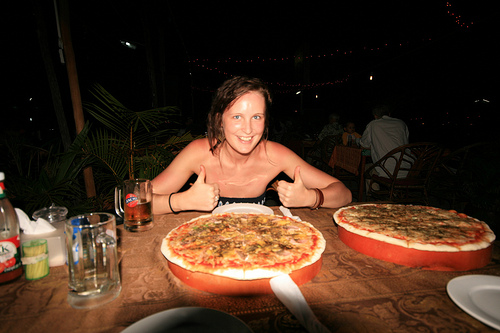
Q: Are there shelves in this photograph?
A: No, there are no shelves.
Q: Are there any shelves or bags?
A: No, there are no shelves or bags.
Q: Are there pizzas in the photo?
A: Yes, there is a pizza.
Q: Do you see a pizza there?
A: Yes, there is a pizza.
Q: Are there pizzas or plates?
A: Yes, there is a pizza.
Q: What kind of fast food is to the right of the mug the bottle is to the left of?
A: The food is a pizza.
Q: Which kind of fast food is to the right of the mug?
A: The food is a pizza.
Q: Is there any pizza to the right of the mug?
A: Yes, there is a pizza to the right of the mug.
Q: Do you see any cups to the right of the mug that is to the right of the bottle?
A: No, there is a pizza to the right of the mug.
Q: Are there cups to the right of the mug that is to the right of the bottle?
A: No, there is a pizza to the right of the mug.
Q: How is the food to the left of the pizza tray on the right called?
A: The food is a pizza.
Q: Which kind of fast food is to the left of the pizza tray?
A: The food is a pizza.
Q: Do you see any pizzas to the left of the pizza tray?
A: Yes, there is a pizza to the left of the pizza tray.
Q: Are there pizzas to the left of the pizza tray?
A: Yes, there is a pizza to the left of the pizza tray.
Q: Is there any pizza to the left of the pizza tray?
A: Yes, there is a pizza to the left of the pizza tray.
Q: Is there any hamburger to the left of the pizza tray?
A: No, there is a pizza to the left of the pizza tray.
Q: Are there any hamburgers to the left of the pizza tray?
A: No, there is a pizza to the left of the pizza tray.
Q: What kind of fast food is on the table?
A: The food is a pizza.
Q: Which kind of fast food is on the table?
A: The food is a pizza.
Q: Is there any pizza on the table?
A: Yes, there is a pizza on the table.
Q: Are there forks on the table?
A: No, there is a pizza on the table.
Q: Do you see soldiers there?
A: No, there are no soldiers.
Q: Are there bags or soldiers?
A: No, there are no soldiers or bags.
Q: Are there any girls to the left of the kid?
A: Yes, there is a girl to the left of the kid.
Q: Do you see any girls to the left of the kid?
A: Yes, there is a girl to the left of the kid.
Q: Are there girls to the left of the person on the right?
A: Yes, there is a girl to the left of the kid.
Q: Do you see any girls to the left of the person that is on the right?
A: Yes, there is a girl to the left of the kid.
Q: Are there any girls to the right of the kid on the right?
A: No, the girl is to the left of the child.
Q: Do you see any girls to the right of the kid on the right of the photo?
A: No, the girl is to the left of the child.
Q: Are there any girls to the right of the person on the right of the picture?
A: No, the girl is to the left of the child.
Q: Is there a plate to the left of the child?
A: No, there is a girl to the left of the child.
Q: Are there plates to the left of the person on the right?
A: No, there is a girl to the left of the child.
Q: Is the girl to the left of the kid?
A: Yes, the girl is to the left of the kid.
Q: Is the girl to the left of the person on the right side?
A: Yes, the girl is to the left of the kid.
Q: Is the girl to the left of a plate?
A: No, the girl is to the left of the kid.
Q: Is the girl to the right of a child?
A: No, the girl is to the left of a child.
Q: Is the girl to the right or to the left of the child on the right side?
A: The girl is to the left of the kid.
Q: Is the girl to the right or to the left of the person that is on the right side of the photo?
A: The girl is to the left of the kid.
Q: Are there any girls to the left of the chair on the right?
A: Yes, there is a girl to the left of the chair.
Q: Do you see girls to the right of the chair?
A: No, the girl is to the left of the chair.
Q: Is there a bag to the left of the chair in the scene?
A: No, there is a girl to the left of the chair.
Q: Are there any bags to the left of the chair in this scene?
A: No, there is a girl to the left of the chair.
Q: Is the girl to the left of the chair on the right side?
A: Yes, the girl is to the left of the chair.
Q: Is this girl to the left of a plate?
A: No, the girl is to the left of the chair.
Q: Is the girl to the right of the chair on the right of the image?
A: No, the girl is to the left of the chair.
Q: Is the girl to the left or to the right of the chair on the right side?
A: The girl is to the left of the chair.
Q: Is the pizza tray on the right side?
A: Yes, the pizza tray is on the right of the image.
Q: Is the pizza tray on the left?
A: No, the pizza tray is on the right of the image.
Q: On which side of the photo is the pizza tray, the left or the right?
A: The pizza tray is on the right of the image.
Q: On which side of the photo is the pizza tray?
A: The pizza tray is on the right of the image.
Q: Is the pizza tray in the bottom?
A: Yes, the pizza tray is in the bottom of the image.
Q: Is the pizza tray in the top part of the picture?
A: No, the pizza tray is in the bottom of the image.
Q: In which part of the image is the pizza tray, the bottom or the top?
A: The pizza tray is in the bottom of the image.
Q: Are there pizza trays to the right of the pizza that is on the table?
A: Yes, there is a pizza tray to the right of the pizza.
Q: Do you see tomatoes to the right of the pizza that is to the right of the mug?
A: No, there is a pizza tray to the right of the pizza.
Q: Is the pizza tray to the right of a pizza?
A: Yes, the pizza tray is to the right of a pizza.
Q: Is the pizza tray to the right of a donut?
A: No, the pizza tray is to the right of a pizza.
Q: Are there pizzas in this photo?
A: Yes, there is a pizza.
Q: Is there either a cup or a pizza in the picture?
A: Yes, there is a pizza.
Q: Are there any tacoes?
A: No, there are no tacoes.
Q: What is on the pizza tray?
A: The pizza is on the pizza tray.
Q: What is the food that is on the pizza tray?
A: The food is a pizza.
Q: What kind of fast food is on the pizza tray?
A: The food is a pizza.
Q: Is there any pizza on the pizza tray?
A: Yes, there is a pizza on the pizza tray.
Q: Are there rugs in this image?
A: No, there are no rugs.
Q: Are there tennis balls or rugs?
A: No, there are no rugs or tennis balls.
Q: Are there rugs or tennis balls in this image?
A: No, there are no rugs or tennis balls.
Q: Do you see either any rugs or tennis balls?
A: No, there are no rugs or tennis balls.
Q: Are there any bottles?
A: Yes, there is a bottle.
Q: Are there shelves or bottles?
A: Yes, there is a bottle.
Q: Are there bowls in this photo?
A: No, there are no bowls.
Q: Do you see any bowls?
A: No, there are no bowls.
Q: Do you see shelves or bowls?
A: No, there are no bowls or shelves.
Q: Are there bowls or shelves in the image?
A: No, there are no bowls or shelves.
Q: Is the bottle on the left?
A: Yes, the bottle is on the left of the image.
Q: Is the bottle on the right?
A: No, the bottle is on the left of the image.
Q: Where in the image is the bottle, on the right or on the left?
A: The bottle is on the left of the image.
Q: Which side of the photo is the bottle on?
A: The bottle is on the left of the image.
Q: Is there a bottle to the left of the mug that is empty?
A: Yes, there is a bottle to the left of the mug.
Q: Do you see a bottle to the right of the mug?
A: No, the bottle is to the left of the mug.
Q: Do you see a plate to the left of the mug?
A: No, there is a bottle to the left of the mug.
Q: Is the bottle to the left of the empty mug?
A: Yes, the bottle is to the left of the mug.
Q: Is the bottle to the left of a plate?
A: No, the bottle is to the left of the mug.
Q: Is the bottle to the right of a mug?
A: No, the bottle is to the left of a mug.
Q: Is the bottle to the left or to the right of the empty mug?
A: The bottle is to the left of the mug.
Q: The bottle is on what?
A: The bottle is on the table.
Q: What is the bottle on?
A: The bottle is on the table.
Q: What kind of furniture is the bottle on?
A: The bottle is on the table.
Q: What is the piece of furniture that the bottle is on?
A: The piece of furniture is a table.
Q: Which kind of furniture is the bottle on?
A: The bottle is on the table.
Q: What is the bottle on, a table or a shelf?
A: The bottle is on a table.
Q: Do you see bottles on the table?
A: Yes, there is a bottle on the table.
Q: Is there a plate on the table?
A: No, there is a bottle on the table.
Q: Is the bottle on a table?
A: Yes, the bottle is on a table.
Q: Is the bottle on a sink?
A: No, the bottle is on a table.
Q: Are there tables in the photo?
A: Yes, there is a table.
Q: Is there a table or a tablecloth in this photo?
A: Yes, there is a table.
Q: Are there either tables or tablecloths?
A: Yes, there is a table.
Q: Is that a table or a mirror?
A: That is a table.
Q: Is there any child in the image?
A: Yes, there is a child.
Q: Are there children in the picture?
A: Yes, there is a child.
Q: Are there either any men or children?
A: Yes, there is a child.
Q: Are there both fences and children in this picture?
A: No, there is a child but no fences.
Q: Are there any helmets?
A: No, there are no helmets.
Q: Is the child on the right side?
A: Yes, the child is on the right of the image.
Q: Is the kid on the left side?
A: No, the kid is on the right of the image.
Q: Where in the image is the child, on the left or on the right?
A: The child is on the right of the image.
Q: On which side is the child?
A: The child is on the right of the image.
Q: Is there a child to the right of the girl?
A: Yes, there is a child to the right of the girl.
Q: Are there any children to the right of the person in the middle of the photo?
A: Yes, there is a child to the right of the girl.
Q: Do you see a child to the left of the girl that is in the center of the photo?
A: No, the child is to the right of the girl.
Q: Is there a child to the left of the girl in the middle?
A: No, the child is to the right of the girl.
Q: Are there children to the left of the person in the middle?
A: No, the child is to the right of the girl.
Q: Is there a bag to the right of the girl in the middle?
A: No, there is a child to the right of the girl.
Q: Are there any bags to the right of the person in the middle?
A: No, there is a child to the right of the girl.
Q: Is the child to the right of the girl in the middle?
A: Yes, the child is to the right of the girl.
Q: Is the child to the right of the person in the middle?
A: Yes, the child is to the right of the girl.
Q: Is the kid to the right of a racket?
A: No, the kid is to the right of the girl.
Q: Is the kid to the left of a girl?
A: No, the kid is to the right of a girl.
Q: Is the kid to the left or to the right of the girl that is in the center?
A: The kid is to the right of the girl.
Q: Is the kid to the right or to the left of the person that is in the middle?
A: The kid is to the right of the girl.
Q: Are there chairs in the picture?
A: Yes, there is a chair.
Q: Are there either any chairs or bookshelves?
A: Yes, there is a chair.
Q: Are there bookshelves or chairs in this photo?
A: Yes, there is a chair.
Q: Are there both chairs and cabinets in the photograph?
A: No, there is a chair but no cabinets.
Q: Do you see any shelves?
A: No, there are no shelves.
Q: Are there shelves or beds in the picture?
A: No, there are no shelves or beds.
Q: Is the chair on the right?
A: Yes, the chair is on the right of the image.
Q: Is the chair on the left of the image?
A: No, the chair is on the right of the image.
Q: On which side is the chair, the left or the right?
A: The chair is on the right of the image.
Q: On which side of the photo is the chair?
A: The chair is on the right of the image.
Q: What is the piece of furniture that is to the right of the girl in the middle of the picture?
A: The piece of furniture is a chair.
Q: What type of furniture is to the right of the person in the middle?
A: The piece of furniture is a chair.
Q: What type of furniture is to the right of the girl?
A: The piece of furniture is a chair.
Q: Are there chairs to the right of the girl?
A: Yes, there is a chair to the right of the girl.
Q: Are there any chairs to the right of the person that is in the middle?
A: Yes, there is a chair to the right of the girl.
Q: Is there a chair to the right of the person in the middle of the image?
A: Yes, there is a chair to the right of the girl.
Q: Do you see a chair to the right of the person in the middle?
A: Yes, there is a chair to the right of the girl.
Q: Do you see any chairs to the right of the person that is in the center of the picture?
A: Yes, there is a chair to the right of the girl.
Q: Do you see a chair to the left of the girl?
A: No, the chair is to the right of the girl.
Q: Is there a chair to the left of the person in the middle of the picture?
A: No, the chair is to the right of the girl.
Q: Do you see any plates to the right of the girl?
A: No, there is a chair to the right of the girl.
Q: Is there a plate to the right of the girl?
A: No, there is a chair to the right of the girl.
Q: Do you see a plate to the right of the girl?
A: No, there is a chair to the right of the girl.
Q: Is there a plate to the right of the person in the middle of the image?
A: No, there is a chair to the right of the girl.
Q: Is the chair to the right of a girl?
A: Yes, the chair is to the right of a girl.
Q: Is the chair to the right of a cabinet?
A: No, the chair is to the right of a girl.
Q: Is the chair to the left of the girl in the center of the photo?
A: No, the chair is to the right of the girl.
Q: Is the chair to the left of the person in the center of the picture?
A: No, the chair is to the right of the girl.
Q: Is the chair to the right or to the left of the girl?
A: The chair is to the right of the girl.